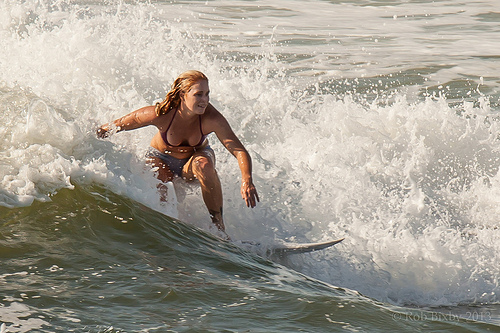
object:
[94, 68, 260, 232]
surfer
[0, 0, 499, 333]
ocean